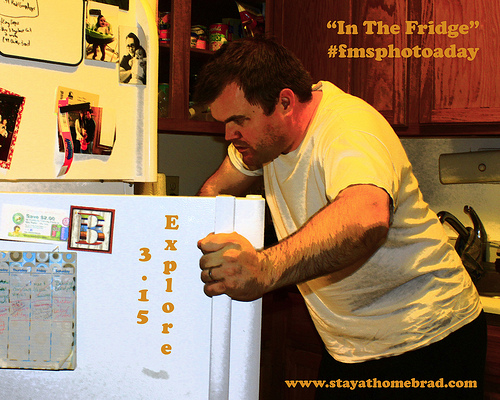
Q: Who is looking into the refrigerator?
A: The man.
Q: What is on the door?
A: Letters.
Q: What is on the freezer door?
A: Photos.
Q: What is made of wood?
A: Cabinets.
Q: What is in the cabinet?
A: Food.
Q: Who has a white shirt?
A: The man.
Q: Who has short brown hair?
A: The man.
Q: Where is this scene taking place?
A: In a kitchen.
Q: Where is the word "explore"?
A: Front of refrigerator by handle.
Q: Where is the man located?
A: Right half of the picture.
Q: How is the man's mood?
A: Hungry.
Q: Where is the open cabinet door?
A: Above man's head to the left.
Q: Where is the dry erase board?
A: Upper middle of the freezer door.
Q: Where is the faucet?
A: Behind man, middle right.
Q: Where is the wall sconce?
A: Above fawcett on the right.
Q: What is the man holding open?
A: Fridge door.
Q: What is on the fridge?
A: Pictures.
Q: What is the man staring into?
A: Fridge.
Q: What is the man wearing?
A: White shirt.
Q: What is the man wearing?
A: White shirt.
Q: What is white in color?
A: The shirt.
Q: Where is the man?
A: In a kitchen.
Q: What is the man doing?
A: Looking in the fridge.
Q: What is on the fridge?
A: Magnets.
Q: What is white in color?
A: The wall.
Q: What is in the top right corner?
A: Words.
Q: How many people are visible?
A: One.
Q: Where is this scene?
A: A kitchen.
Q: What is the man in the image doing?
A: Looking in the fridge.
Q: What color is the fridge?
A: White.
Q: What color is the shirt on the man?
A: White.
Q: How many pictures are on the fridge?
A: Four.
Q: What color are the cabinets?
A: Brown.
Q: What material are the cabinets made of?
A: Wood.